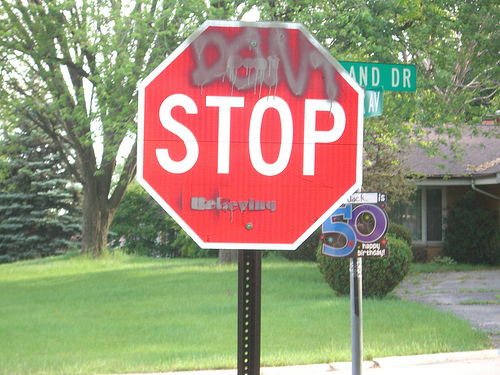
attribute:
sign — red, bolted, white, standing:
[134, 20, 369, 252]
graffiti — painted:
[182, 25, 343, 100]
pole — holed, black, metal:
[236, 246, 264, 374]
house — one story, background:
[380, 120, 500, 264]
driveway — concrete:
[392, 268, 499, 352]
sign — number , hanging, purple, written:
[322, 195, 389, 263]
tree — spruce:
[0, 96, 86, 267]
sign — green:
[337, 56, 419, 119]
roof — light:
[395, 119, 499, 175]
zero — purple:
[353, 203, 390, 247]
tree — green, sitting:
[320, 230, 418, 301]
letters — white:
[153, 88, 346, 178]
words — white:
[356, 237, 387, 259]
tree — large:
[0, 2, 208, 263]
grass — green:
[1, 249, 495, 374]